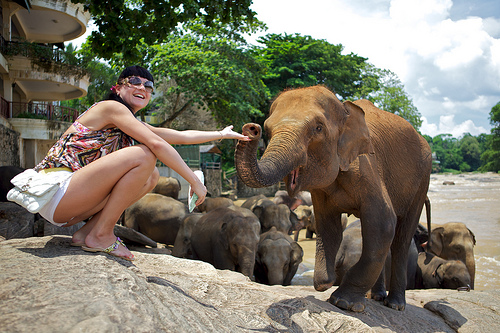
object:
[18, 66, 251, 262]
woman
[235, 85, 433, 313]
elephant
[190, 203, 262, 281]
elephants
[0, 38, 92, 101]
balcony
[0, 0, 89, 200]
building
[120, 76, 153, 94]
sunglasses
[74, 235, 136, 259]
flip flops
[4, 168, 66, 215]
purse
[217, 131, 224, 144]
bracelet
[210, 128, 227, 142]
wrist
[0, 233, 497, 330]
rock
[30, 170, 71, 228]
shorts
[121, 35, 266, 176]
trees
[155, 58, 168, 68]
leaves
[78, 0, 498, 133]
sky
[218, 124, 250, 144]
hand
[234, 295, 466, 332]
shadow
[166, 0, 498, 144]
clouds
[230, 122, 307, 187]
nose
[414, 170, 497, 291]
river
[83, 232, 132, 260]
feet